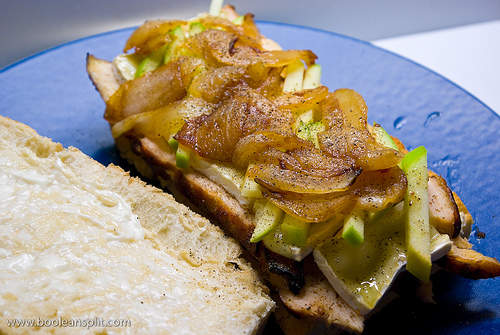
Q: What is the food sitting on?
A: Blue plate.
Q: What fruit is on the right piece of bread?
A: Apples.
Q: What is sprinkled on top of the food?
A: Pepper.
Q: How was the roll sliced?
A: In half.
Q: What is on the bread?
A: Cheese.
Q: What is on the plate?
A: Food.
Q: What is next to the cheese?
A: Piece of bread.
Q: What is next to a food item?
A: Plate.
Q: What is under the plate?
A: Table.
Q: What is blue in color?
A: Plate.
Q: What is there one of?
A: Sandwich.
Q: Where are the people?
A: No people.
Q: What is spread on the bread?
A: Cheese.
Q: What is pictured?
A: A sandwich.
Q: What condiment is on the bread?
A: Mayonnaise.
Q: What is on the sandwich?
A: Grilled onions.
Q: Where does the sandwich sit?
A: On a blue plate.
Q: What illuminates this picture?
A: Indoor lighting.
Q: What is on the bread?
A: Grilled green vegetables.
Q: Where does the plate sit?
A: On a table.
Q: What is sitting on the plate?
A: Food.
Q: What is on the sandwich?
A: Vegetables.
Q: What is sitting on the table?
A: The plate.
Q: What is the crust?
A: Brown.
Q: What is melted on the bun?
A: Cheese.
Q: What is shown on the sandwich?
A: Onions.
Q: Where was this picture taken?
A: A kitchen.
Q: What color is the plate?
A: Blue.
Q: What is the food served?
A: A plate.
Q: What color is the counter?
A: Aqua.